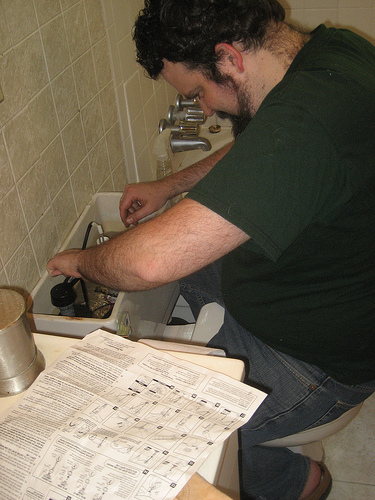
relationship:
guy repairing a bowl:
[45, 0, 375, 500] [24, 190, 181, 339]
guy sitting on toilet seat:
[45, 0, 375, 500] [187, 300, 364, 433]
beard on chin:
[215, 88, 254, 127] [184, 71, 279, 123]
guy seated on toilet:
[122, 7, 354, 296] [281, 433, 343, 447]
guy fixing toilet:
[45, 0, 375, 500] [21, 188, 363, 466]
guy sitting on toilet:
[45, 0, 375, 500] [21, 188, 363, 466]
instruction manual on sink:
[3, 330, 266, 498] [30, 330, 75, 368]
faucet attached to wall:
[167, 135, 211, 152] [146, 85, 211, 154]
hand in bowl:
[34, 247, 87, 292] [17, 185, 187, 350]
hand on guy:
[34, 247, 87, 292] [45, 0, 375, 500]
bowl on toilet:
[17, 185, 187, 350] [16, 186, 236, 353]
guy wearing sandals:
[45, 0, 375, 500] [294, 449, 337, 491]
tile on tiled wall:
[10, 152, 59, 236] [1, 1, 182, 300]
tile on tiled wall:
[55, 106, 94, 177] [1, 1, 182, 300]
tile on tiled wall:
[59, 1, 98, 69] [1, 1, 182, 300]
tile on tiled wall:
[89, 33, 114, 94] [1, 1, 182, 300]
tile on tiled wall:
[102, 116, 130, 176] [1, 1, 182, 300]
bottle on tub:
[154, 128, 176, 180] [169, 123, 232, 169]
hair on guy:
[129, 0, 286, 87] [45, 0, 375, 500]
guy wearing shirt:
[45, 0, 375, 500] [120, 21, 373, 354]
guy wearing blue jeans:
[45, 0, 375, 500] [167, 225, 371, 498]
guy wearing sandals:
[45, 0, 375, 500] [307, 460, 333, 498]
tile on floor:
[322, 392, 373, 482] [321, 392, 374, 499]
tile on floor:
[329, 481, 374, 498] [321, 392, 374, 499]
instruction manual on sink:
[3, 330, 266, 498] [34, 335, 73, 354]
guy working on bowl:
[45, 0, 375, 500] [24, 190, 181, 339]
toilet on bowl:
[21, 188, 363, 466] [24, 190, 181, 339]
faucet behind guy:
[159, 93, 210, 150] [45, 0, 375, 500]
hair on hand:
[123, 0, 291, 87] [44, 237, 95, 287]